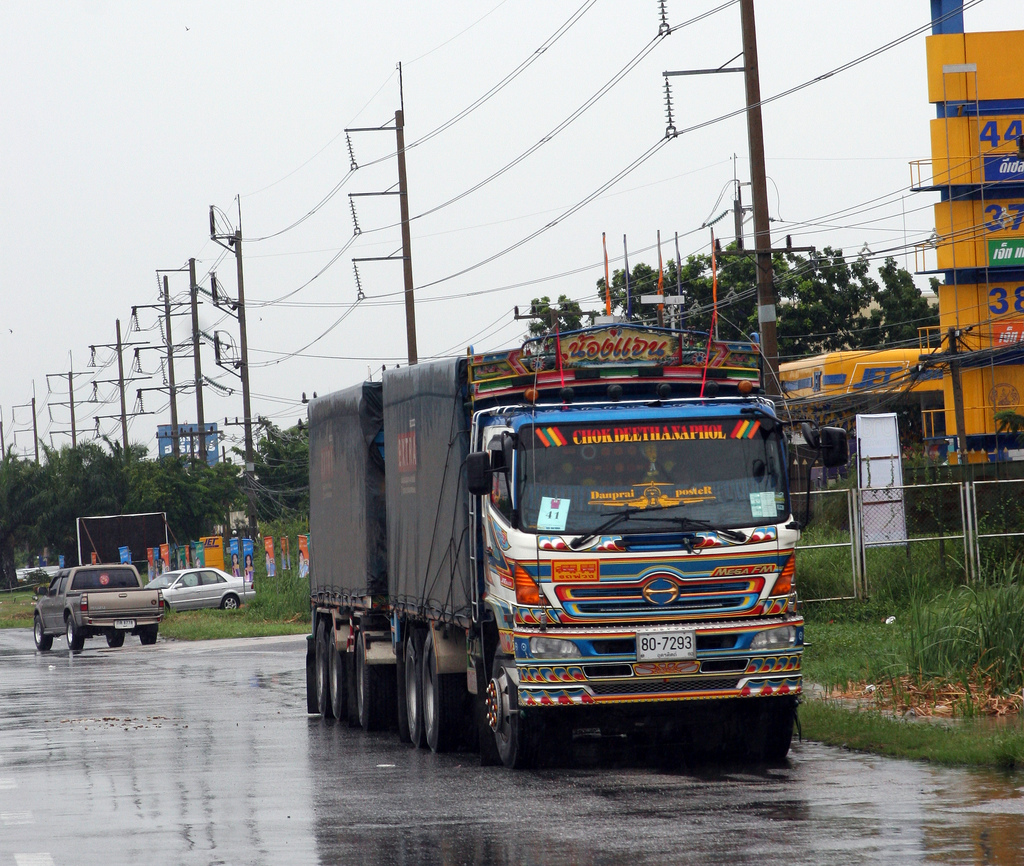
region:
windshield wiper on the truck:
[547, 489, 759, 567]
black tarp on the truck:
[373, 353, 485, 625]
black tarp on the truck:
[278, 376, 392, 618]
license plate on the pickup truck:
[108, 619, 135, 632]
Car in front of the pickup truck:
[144, 562, 253, 610]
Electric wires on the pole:
[340, 91, 418, 310]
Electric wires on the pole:
[187, 198, 255, 404]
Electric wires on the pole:
[108, 290, 184, 414]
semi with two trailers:
[233, 344, 845, 791]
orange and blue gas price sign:
[909, 2, 1021, 465]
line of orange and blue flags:
[6, 542, 320, 593]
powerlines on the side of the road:
[2, 8, 973, 531]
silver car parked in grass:
[123, 558, 269, 619]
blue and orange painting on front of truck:
[492, 398, 812, 724]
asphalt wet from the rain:
[6, 615, 1021, 862]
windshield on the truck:
[508, 429, 794, 546]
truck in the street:
[280, 322, 821, 776]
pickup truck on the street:
[34, 564, 178, 656]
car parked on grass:
[144, 567, 262, 612]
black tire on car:
[214, 594, 244, 614]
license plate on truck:
[632, 628, 697, 663]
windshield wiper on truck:
[575, 498, 693, 541]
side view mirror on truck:
[449, 450, 501, 502]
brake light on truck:
[73, 594, 93, 620]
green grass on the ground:
[805, 694, 1022, 770]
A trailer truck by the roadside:
[308, 327, 799, 761]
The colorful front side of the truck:
[471, 329, 801, 710]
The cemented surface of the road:
[6, 616, 1021, 860]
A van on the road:
[36, 562, 163, 654]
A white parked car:
[151, 559, 251, 616]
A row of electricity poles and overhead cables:
[3, 6, 1019, 458]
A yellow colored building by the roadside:
[924, 6, 1023, 478]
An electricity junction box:
[853, 408, 910, 548]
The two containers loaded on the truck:
[304, 357, 476, 615]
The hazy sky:
[6, 172, 962, 449]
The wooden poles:
[15, 206, 822, 381]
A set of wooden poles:
[5, 183, 966, 419]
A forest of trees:
[40, 246, 910, 544]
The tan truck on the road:
[21, 542, 178, 664]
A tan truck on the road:
[19, 541, 171, 656]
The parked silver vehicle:
[138, 539, 274, 638]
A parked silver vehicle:
[137, 535, 274, 625]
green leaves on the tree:
[838, 273, 861, 299]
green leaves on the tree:
[787, 277, 825, 331]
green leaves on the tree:
[171, 501, 219, 524]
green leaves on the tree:
[170, 473, 240, 500]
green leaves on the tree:
[132, 467, 175, 502]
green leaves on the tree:
[45, 482, 91, 527]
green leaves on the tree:
[255, 432, 279, 464]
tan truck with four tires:
[28, 559, 166, 651]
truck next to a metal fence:
[300, 319, 1021, 769]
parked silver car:
[145, 565, 256, 617]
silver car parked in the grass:
[143, 568, 314, 641]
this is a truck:
[307, 316, 810, 814]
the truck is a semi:
[387, 307, 840, 783]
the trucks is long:
[219, 294, 631, 766]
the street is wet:
[87, 622, 367, 838]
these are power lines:
[171, 181, 666, 347]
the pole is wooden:
[289, 98, 476, 387]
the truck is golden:
[32, 485, 236, 713]